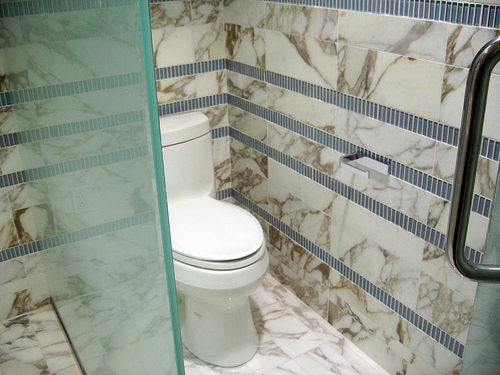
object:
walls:
[30, 57, 152, 194]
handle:
[456, 39, 500, 283]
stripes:
[317, 91, 451, 137]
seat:
[176, 232, 278, 298]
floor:
[272, 322, 329, 375]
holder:
[339, 154, 391, 184]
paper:
[336, 151, 398, 181]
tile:
[273, 312, 330, 365]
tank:
[150, 133, 222, 196]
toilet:
[169, 133, 288, 308]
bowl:
[181, 245, 272, 303]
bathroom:
[32, 22, 451, 358]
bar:
[443, 49, 496, 262]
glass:
[27, 11, 185, 375]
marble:
[263, 12, 375, 73]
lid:
[176, 210, 238, 248]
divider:
[129, 0, 190, 375]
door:
[407, 0, 499, 375]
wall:
[283, 19, 383, 139]